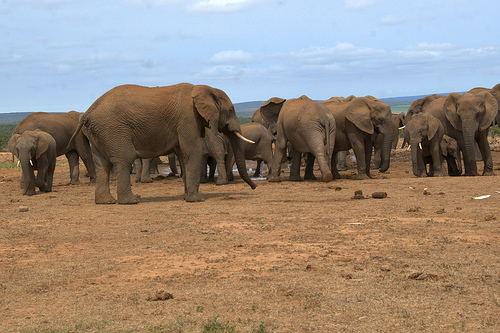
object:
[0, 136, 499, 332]
grass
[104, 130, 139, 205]
leg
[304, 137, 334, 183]
leg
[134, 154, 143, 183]
leg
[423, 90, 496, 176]
elephants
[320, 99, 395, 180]
elephants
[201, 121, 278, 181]
elephants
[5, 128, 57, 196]
baby elephant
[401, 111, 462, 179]
elephant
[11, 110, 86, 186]
elephant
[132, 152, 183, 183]
elephant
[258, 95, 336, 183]
elephant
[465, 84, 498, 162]
elephant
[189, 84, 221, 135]
big ear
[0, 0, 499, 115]
cloud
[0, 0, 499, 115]
sky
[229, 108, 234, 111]
elephant eye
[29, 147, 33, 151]
elephant eye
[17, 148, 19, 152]
elephant eye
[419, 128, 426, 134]
elephant eye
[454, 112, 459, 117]
elephant eye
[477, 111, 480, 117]
elephant eye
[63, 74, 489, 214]
laptop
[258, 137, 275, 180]
rear legs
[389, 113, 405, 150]
elephant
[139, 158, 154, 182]
leg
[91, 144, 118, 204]
leg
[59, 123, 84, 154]
tail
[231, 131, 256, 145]
tusk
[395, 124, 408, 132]
tusk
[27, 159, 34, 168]
tusk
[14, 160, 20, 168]
tusk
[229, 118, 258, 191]
trunk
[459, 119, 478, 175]
trunk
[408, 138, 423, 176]
trunk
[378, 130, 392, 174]
trunk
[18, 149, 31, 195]
trunk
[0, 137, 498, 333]
dirt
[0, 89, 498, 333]
ground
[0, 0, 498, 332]
background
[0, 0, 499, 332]
photo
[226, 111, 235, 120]
eye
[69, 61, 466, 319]
camers